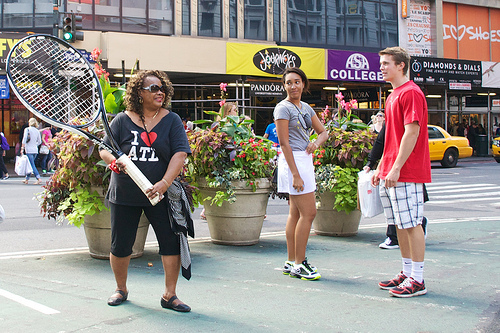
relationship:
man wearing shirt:
[369, 44, 430, 301] [382, 80, 434, 185]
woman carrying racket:
[101, 66, 195, 316] [7, 32, 164, 207]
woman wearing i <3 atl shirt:
[101, 66, 195, 316] [99, 108, 191, 205]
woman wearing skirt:
[271, 66, 332, 281] [273, 148, 319, 198]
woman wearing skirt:
[101, 66, 195, 316] [273, 148, 319, 198]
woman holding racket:
[101, 66, 195, 316] [7, 32, 164, 207]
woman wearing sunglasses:
[101, 66, 195, 316] [137, 83, 168, 94]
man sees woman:
[369, 44, 430, 301] [101, 66, 195, 316]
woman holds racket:
[101, 66, 195, 316] [7, 32, 164, 207]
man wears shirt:
[369, 44, 430, 301] [382, 80, 434, 185]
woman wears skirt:
[101, 66, 195, 316] [273, 148, 319, 198]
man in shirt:
[369, 44, 430, 301] [382, 80, 434, 185]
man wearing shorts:
[369, 44, 430, 301] [378, 177, 428, 229]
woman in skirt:
[271, 66, 332, 281] [273, 148, 319, 198]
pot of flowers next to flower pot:
[182, 113, 280, 246] [42, 113, 156, 256]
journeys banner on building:
[225, 40, 333, 79] [3, 2, 500, 165]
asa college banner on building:
[327, 49, 401, 81] [3, 2, 500, 165]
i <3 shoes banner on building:
[441, 2, 499, 63] [3, 2, 500, 165]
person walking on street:
[18, 116, 43, 188] [1, 158, 498, 253]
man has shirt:
[369, 44, 430, 301] [382, 80, 434, 185]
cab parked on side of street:
[423, 120, 473, 171] [1, 158, 498, 253]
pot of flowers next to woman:
[182, 113, 280, 246] [101, 66, 195, 316]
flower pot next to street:
[42, 113, 156, 256] [1, 158, 498, 253]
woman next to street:
[271, 66, 332, 281] [1, 158, 498, 253]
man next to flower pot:
[369, 44, 430, 301] [42, 113, 156, 256]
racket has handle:
[7, 32, 164, 207] [118, 152, 164, 206]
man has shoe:
[369, 44, 430, 301] [392, 276, 426, 298]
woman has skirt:
[271, 66, 332, 281] [273, 148, 319, 198]